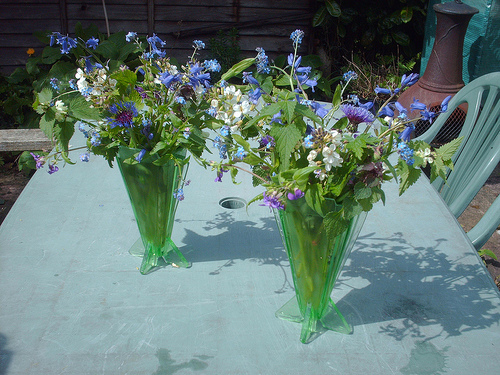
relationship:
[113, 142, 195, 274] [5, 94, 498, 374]
vase on table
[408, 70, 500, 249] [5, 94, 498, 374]
chair next to table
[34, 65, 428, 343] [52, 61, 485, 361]
bench behind table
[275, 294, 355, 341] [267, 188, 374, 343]
feet on vase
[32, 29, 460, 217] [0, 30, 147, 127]
blue flowers in garden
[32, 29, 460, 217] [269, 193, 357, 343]
blue flowers in vase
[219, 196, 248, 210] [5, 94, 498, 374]
hole in middle of table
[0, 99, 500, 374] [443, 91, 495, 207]
bench next to chair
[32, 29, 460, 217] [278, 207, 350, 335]
blue flowers in vase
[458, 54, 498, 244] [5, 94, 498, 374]
chair by table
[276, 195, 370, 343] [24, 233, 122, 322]
vase on top of table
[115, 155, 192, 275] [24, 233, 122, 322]
vase on top of table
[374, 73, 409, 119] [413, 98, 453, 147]
blue flower next to blue flower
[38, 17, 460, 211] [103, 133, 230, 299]
blue flowers in a vase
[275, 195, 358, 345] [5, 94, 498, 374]
vase on a table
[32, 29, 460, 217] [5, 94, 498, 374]
blue flowers on a table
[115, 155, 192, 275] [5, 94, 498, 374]
vase on a table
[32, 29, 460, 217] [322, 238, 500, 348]
blue flowers has a shadow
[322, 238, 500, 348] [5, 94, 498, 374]
shadow on table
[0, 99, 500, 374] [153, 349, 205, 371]
bench has a spot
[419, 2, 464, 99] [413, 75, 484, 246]
fireplace behind a chair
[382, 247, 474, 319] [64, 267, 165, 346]
shadow on a table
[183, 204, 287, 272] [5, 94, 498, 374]
shadow on a table